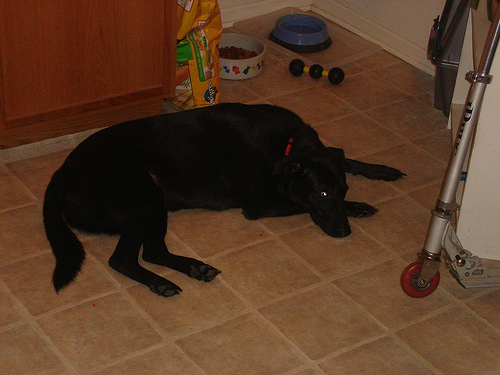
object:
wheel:
[400, 262, 440, 299]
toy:
[289, 58, 345, 85]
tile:
[257, 281, 391, 364]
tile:
[394, 304, 498, 374]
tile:
[202, 238, 324, 309]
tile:
[166, 209, 274, 260]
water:
[284, 20, 319, 33]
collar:
[284, 138, 294, 156]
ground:
[393, 132, 444, 176]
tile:
[34, 290, 167, 375]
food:
[166, 0, 224, 110]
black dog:
[43, 101, 408, 298]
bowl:
[267, 13, 332, 55]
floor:
[0, 7, 500, 375]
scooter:
[398, 0, 500, 298]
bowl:
[209, 33, 267, 81]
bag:
[167, 0, 224, 111]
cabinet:
[0, 0, 178, 150]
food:
[219, 45, 255, 60]